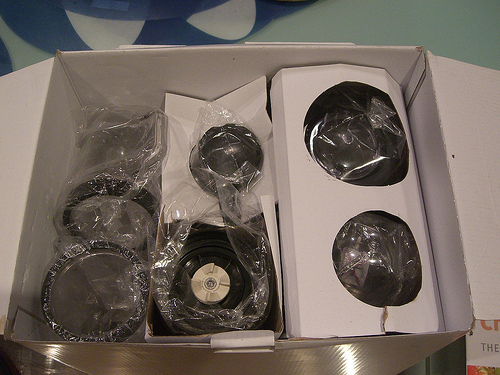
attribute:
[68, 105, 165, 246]
wrap — clear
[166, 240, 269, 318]
blender — clear, large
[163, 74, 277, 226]
cardboard — white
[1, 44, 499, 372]
box — white, illuminated, folded, small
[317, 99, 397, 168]
wrap — clear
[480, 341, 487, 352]
letter — grey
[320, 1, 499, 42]
floor — blue